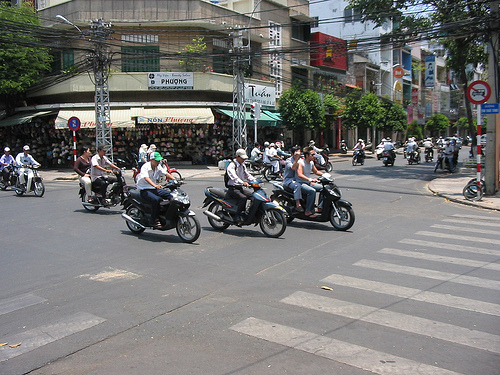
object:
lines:
[1, 308, 109, 367]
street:
[0, 143, 499, 374]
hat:
[150, 151, 164, 162]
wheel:
[175, 213, 200, 243]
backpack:
[225, 160, 238, 189]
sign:
[467, 80, 491, 104]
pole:
[476, 105, 483, 199]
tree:
[344, 0, 500, 174]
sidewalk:
[429, 150, 500, 209]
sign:
[148, 72, 195, 91]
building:
[0, 1, 310, 170]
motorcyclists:
[11, 145, 40, 190]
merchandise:
[2, 114, 48, 142]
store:
[2, 93, 291, 165]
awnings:
[0, 109, 49, 126]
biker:
[91, 145, 123, 204]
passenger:
[74, 145, 94, 202]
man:
[138, 152, 179, 230]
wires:
[0, 0, 481, 22]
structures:
[28, 0, 294, 95]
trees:
[278, 86, 334, 150]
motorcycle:
[78, 169, 136, 212]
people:
[284, 146, 324, 218]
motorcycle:
[270, 179, 356, 231]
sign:
[68, 116, 81, 130]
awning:
[138, 106, 214, 124]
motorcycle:
[122, 184, 203, 245]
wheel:
[125, 206, 148, 234]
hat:
[236, 149, 250, 160]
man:
[300, 147, 328, 219]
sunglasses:
[311, 153, 317, 155]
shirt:
[74, 157, 92, 175]